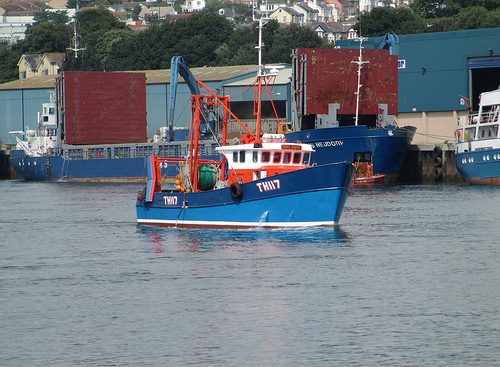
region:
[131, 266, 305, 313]
blue color in the river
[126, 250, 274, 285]
tiny ripples on the water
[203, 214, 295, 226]
white color on the bottom of the boar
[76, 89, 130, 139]
red color on the wall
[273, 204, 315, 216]
blue paint on the boat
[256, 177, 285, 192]
large white letters on the side of boat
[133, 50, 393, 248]
large boat in the water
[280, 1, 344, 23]
houses in the back ground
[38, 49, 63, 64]
sloped roof on building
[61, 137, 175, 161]
blue wall on the shore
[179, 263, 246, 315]
black spot on water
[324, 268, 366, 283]
black spot on water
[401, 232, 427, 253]
black spot on water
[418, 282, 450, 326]
black spot on water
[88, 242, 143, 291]
black spot on water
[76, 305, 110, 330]
black spot on water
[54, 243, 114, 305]
black spot on water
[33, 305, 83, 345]
black spot on water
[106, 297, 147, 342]
black spot on water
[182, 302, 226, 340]
black spot on water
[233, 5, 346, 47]
several white homes in the background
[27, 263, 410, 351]
large lake of water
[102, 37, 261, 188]
blue crain on a fishing boat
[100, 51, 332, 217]
orange equipment placed on a boat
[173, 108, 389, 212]
several windows on a fishing boat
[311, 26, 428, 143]
white equipment on a fishing boat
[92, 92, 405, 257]
the letter t on the side of a fishing boat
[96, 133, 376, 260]
the letter h on the side of a fishing boat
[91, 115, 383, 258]
the number 1 on the side of a blue boat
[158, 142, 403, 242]
the number 7 on the side of a blue boat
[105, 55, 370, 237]
boat on the water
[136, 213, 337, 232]
red and white stripes on the bottom of the boat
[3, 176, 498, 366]
calm body of water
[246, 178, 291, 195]
writing on the side of the boat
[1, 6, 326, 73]
dark green tree tops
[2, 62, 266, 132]
blue building with a brown roof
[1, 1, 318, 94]
tree tops visible over the roof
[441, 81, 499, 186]
blue and white boat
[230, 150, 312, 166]
row of small windows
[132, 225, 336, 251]
reflection in the water